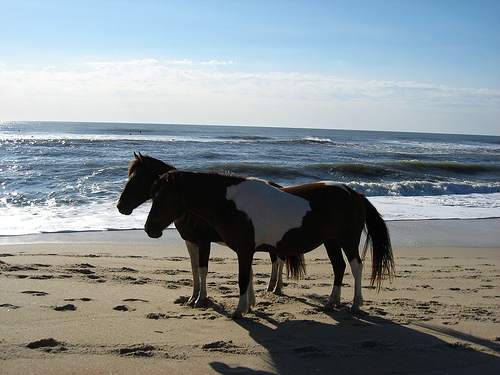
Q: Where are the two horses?
A: Standing on the beach.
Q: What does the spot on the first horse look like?
A: An asymmetrical shape.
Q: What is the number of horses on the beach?
A: 2.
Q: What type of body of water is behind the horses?
A: An ocean.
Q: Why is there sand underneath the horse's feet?
A: Because the horses are at the beach.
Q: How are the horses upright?
A: Because of the thing called a leg.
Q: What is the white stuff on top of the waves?
A: That is referred to as the waves cap.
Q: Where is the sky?
A: Top half of the photo.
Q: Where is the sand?
A: Bottom half of the photo.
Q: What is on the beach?
A: Animals.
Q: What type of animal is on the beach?
A: Horse.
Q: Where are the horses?
A: On the beach.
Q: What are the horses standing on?
A: Sand.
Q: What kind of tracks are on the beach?
A: Horse tracks.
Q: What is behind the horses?
A: Water.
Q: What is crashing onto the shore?
A: Waves.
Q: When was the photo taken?
A: During daylight hours.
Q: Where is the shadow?
A: On the sand.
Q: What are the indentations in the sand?
A: Hoof prints.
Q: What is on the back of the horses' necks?
A: A mane.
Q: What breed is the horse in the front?
A: Pinto.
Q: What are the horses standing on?
A: Sand.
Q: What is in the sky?
A: Clouds.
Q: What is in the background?
A: The ocean.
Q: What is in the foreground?
A: Shadows.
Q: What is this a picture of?
A: 2 horses by the ocean.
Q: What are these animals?
A: Horses.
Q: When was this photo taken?
A: During the daytime.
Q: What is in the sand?
A: Footprints.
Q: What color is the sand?
A: Brown.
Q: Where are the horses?
A: At a beach.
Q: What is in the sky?
A: Clouds.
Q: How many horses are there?
A: Two.